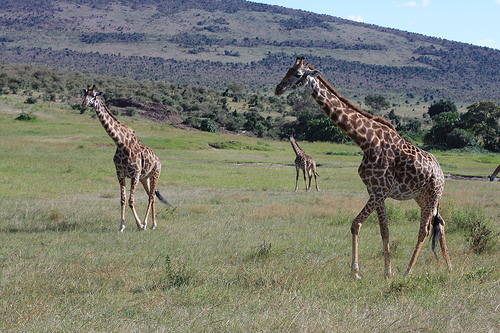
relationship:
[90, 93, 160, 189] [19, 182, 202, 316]
giraffe in a plain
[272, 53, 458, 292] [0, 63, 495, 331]
giraffe in plain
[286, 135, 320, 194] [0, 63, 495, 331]
giraffe in plain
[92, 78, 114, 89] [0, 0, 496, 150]
bushes on hill side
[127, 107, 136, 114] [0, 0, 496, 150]
bushes on hill side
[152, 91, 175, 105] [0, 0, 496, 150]
bushes on hill side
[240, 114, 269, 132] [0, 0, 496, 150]
bushes on hill side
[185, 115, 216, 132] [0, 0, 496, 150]
bushes on hill side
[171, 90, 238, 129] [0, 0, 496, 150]
bushes on hill side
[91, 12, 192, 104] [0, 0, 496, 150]
bushes on hill side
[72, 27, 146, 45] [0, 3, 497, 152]
bushes on hill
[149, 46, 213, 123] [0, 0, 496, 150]
green bushes on hill side